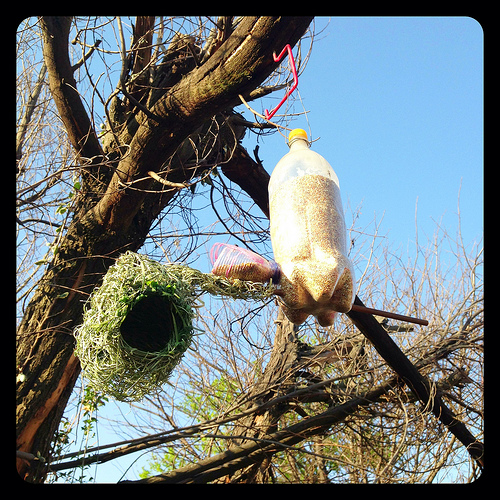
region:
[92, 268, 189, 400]
the net is made of grass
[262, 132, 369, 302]
the bottle is plastic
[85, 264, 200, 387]
the nest is empty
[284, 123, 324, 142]
the top is yellow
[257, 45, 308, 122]
the object is red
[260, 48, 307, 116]
the object is metallic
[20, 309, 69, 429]
the tree is brown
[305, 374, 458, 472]
the trees has no leaves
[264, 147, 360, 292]
the bottle is not empty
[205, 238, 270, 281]
the object is pink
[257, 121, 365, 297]
bottle in a tree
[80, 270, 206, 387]
structure with a hole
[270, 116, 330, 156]
yellow top of bottle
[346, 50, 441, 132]
blue sky above tree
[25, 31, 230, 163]
branches of the tree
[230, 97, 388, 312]
bottle with a yellow top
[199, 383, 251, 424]
green leaves in background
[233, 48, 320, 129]
red thingon the tree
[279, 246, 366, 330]
bottom of the bottle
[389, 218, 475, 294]
many branches of the tree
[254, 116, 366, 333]
bottle hangs from a branch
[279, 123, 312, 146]
cap of the bottle is yellow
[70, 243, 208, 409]
nest in a tree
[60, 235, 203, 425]
nest in a tree is green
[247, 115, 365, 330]
bottle is full of seeds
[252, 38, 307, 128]
hook hangs from tree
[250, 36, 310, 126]
hang is red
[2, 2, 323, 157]
branches of tree do not have leaves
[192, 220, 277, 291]
pink object with seeds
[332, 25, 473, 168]
Sky is blue and clear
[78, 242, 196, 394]
LARGE GREEN BIRD NEST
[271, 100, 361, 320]
TWO LITER BOTTLE OF SODA WITH FEED INSIDE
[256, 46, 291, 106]
RED METAL HOOK ON TREE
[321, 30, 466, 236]
CLEAR BRIGHT BLUE SKY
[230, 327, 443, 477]
LEAVELESS BRANCHES ON TREE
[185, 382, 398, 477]
GREEN LEAVES ON TREE IN BACKGROUND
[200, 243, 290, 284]
PLASTIC UP ON BRANCH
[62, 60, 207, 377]
LARGE BROWN LEAVELESS TREE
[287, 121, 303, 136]
YELLOW CAP OF TWO LITER BOTTLE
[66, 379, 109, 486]
VINES HANGING FROM TREE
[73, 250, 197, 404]
green and yellow bird house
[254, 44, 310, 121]
red hook stuck in the tree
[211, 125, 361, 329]
large bird feeder bottle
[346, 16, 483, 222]
clear, blue sky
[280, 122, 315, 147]
yellow bottle cap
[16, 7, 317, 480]
big brown tree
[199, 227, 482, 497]
tree branches are barren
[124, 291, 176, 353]
dark hole in bird house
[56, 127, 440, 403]
bird house attached to bird feeder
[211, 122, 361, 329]
bird feeder filled with bird seed